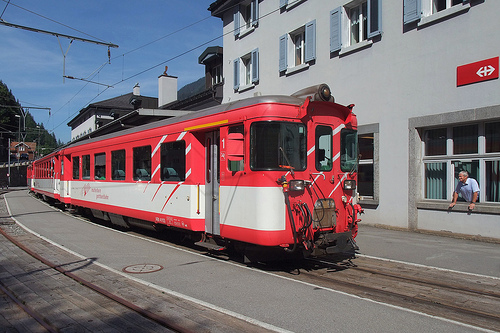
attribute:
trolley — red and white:
[5, 83, 364, 273]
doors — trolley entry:
[198, 127, 225, 239]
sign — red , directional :
[453, 63, 483, 85]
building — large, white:
[206, 5, 485, 226]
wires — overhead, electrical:
[35, 13, 293, 91]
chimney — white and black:
[154, 72, 182, 104]